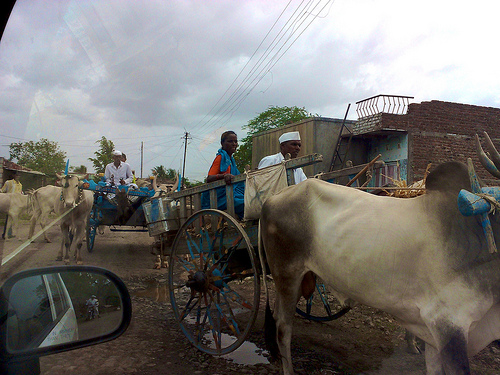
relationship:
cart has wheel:
[106, 144, 397, 347] [168, 222, 292, 343]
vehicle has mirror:
[18, 273, 89, 339] [8, 253, 127, 352]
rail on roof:
[343, 99, 408, 109] [340, 93, 499, 131]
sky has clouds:
[23, 9, 485, 85] [28, 25, 226, 113]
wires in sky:
[206, 1, 325, 119] [23, 9, 485, 85]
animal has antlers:
[263, 170, 498, 366] [457, 124, 497, 215]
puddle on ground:
[195, 297, 271, 363] [119, 257, 340, 370]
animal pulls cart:
[263, 170, 498, 366] [106, 144, 397, 347]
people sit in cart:
[197, 125, 312, 192] [106, 144, 397, 347]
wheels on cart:
[170, 204, 349, 343] [106, 144, 397, 347]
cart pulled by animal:
[106, 144, 397, 347] [263, 170, 498, 366]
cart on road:
[106, 144, 397, 347] [36, 223, 157, 276]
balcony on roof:
[316, 80, 410, 130] [340, 93, 499, 131]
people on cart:
[197, 125, 312, 192] [106, 144, 397, 347]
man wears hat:
[262, 130, 306, 195] [279, 124, 296, 145]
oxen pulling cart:
[11, 177, 92, 268] [87, 152, 173, 251]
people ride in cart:
[197, 125, 312, 192] [106, 144, 397, 347]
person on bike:
[85, 294, 99, 307] [83, 304, 109, 328]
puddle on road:
[195, 297, 271, 363] [36, 223, 157, 276]